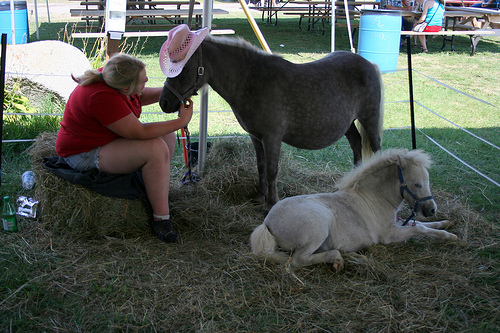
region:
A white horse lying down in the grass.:
[251, 148, 462, 288]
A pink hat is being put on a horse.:
[153, 13, 217, 79]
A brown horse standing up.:
[157, 20, 413, 207]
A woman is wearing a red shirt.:
[44, 50, 209, 249]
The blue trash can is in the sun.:
[349, 3, 417, 72]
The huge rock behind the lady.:
[7, 25, 102, 113]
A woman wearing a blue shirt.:
[415, 6, 458, 55]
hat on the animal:
[137, 15, 222, 75]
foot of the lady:
[140, 190, 186, 257]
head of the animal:
[366, 130, 447, 240]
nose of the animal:
[412, 187, 447, 224]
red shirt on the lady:
[40, 75, 131, 155]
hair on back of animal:
[185, 25, 280, 70]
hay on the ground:
[136, 235, 234, 310]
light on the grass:
[418, 57, 486, 115]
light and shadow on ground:
[418, 105, 477, 162]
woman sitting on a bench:
[397, 1, 494, 53]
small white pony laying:
[251, 144, 457, 271]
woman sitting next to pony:
[55, 23, 385, 243]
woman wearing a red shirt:
[55, 53, 195, 244]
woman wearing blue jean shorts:
[53, 56, 195, 244]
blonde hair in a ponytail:
[69, 51, 146, 99]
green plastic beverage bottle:
[2, 193, 21, 235]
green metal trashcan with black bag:
[356, 7, 400, 74]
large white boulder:
[7, 35, 92, 122]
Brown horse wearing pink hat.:
[155, 24, 426, 226]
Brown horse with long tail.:
[156, 18, 413, 215]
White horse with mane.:
[248, 142, 467, 289]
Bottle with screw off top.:
[0, 187, 22, 244]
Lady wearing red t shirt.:
[43, 47, 193, 244]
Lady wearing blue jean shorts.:
[44, 54, 191, 257]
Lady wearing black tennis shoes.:
[54, 53, 198, 242]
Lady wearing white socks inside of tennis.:
[49, 50, 190, 265]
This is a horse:
[240, 142, 485, 259]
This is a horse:
[147, 13, 397, 176]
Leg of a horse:
[261, 130, 286, 211]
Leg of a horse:
[337, 112, 374, 188]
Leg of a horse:
[365, 97, 387, 168]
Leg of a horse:
[286, 221, 346, 283]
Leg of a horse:
[379, 213, 458, 247]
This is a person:
[51, 48, 211, 260]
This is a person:
[410, 0, 458, 61]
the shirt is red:
[41, 79, 144, 164]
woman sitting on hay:
[56, 74, 185, 239]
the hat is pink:
[148, 24, 212, 78]